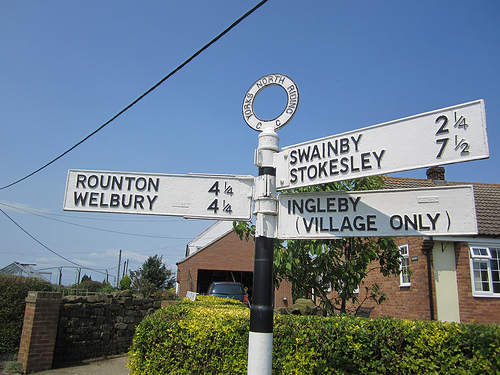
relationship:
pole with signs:
[239, 71, 300, 375] [43, 82, 488, 252]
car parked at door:
[205, 279, 250, 307] [193, 267, 253, 305]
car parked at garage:
[205, 279, 250, 307] [171, 223, 293, 310]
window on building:
[468, 244, 499, 301] [155, 183, 483, 317]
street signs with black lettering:
[62, 95, 490, 244] [73, 109, 468, 230]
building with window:
[171, 164, 498, 332] [312, 257, 334, 294]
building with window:
[171, 164, 498, 332] [389, 243, 417, 290]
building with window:
[171, 164, 498, 332] [462, 239, 498, 299]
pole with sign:
[239, 71, 300, 375] [52, 150, 233, 222]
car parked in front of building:
[205, 279, 252, 307] [168, 211, 260, 309]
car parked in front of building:
[205, 279, 252, 307] [297, 166, 499, 321]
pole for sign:
[225, 56, 326, 361] [272, 190, 475, 237]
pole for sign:
[225, 56, 326, 361] [277, 101, 484, 183]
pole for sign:
[225, 56, 326, 361] [58, 166, 250, 221]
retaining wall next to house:
[17, 289, 145, 369] [190, 165, 497, 334]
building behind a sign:
[173, 179, 294, 311] [56, 66, 499, 245]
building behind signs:
[173, 179, 294, 311] [61, 72, 491, 240]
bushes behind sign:
[127, 294, 496, 371] [267, 185, 483, 240]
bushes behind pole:
[127, 294, 496, 371] [244, 65, 291, 373]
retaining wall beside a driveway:
[52, 300, 121, 368] [39, 349, 126, 373]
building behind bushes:
[173, 179, 294, 311] [127, 294, 496, 371]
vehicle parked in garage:
[198, 267, 273, 321] [193, 267, 253, 307]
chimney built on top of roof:
[425, 165, 445, 179] [358, 176, 499, 226]